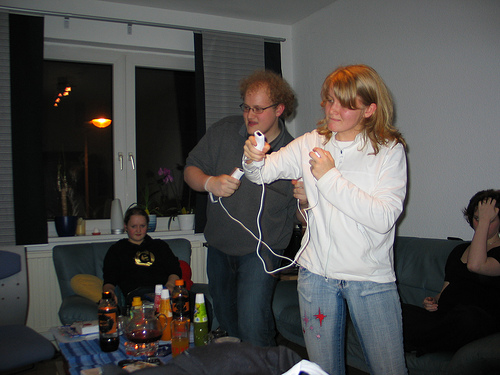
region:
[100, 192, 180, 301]
a person sitting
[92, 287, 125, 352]
a bottle on the table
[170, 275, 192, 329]
a bottle on the table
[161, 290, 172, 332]
a bottle on the table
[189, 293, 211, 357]
a bottle on the table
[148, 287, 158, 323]
a bottle on the table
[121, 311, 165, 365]
a glass on the table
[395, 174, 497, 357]
a person is sitting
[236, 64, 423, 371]
a person is standing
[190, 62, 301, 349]
a person is standing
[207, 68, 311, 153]
man with blond curly hair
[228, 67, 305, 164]
man with wire rim glasses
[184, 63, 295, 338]
man holding wii hand held device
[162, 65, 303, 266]
man wearing gray short sleeve pullover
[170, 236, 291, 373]
man wearing blue jeans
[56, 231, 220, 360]
all types of drinks on the table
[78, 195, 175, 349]
girl sitting down on sofa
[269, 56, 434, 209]
girl with long blond hair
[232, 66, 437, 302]
girl wearing white long sleeve jacket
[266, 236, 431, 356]
girl wearing blue jeans with red star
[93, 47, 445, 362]
playing video games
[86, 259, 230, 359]
alcohol for a party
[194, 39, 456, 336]
man and woman standing up to play video games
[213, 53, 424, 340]
man and woman playing video games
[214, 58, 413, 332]
man and woman playing nintendo wii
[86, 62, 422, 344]
woman watching friends play video games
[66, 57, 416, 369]
video game party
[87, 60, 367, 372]
drinking and playing video games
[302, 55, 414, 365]
blond woman in white sweat shirt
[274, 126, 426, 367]
white sweat shirt and blue jeans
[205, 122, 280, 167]
A white Wii controller.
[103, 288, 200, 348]
Many beverages on the table.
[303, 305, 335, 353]
A woman's jeans decorated with red star.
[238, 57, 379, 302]
Two people standing playing with a Wii console.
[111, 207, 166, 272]
A young woman staring at the camera.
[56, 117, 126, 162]
A Light seen through the dark window.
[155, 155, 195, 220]
purple flowers in a white vase.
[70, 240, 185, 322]
A woman sitting on a blue sofa.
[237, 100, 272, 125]
A young man wearing glasses.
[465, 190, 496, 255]
A young person combing dark hair with a hand.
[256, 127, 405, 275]
a white top is worn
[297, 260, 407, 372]
a pair of blue jeans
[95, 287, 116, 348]
a bottle on a table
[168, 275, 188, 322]
a bottle on a table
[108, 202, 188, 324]
a person is sitting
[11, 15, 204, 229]
a window in the house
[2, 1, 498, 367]
it is an indoor scene